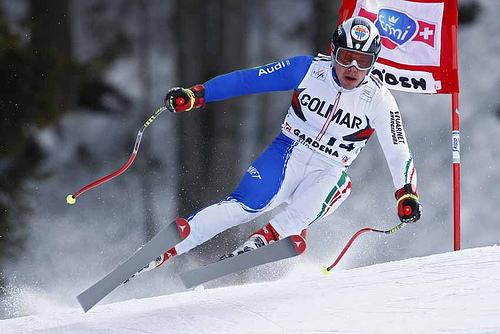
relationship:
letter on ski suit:
[305, 95, 321, 115] [207, 41, 437, 261]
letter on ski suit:
[315, 99, 334, 118] [141, 47, 461, 294]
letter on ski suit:
[310, 93, 318, 112] [111, 27, 462, 258]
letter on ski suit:
[338, 117, 350, 130] [174, 32, 444, 270]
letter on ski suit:
[348, 114, 361, 134] [158, 41, 424, 255]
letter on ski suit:
[288, 120, 302, 143] [135, 19, 440, 268]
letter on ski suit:
[302, 129, 305, 144] [188, 51, 459, 285]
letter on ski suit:
[305, 136, 322, 138] [193, 50, 438, 270]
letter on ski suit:
[310, 137, 319, 153] [177, 57, 432, 267]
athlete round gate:
[121, 16, 423, 295] [126, 3, 471, 283]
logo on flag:
[375, 8, 420, 51] [330, 1, 466, 99]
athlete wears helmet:
[121, 16, 423, 295] [326, 10, 384, 71]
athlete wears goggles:
[121, 16, 423, 295] [328, 46, 375, 71]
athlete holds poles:
[121, 16, 423, 295] [52, 81, 421, 281]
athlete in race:
[121, 16, 423, 295] [6, 4, 498, 331]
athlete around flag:
[121, 16, 423, 295] [328, 1, 468, 261]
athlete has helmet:
[121, 16, 423, 295] [324, 4, 389, 73]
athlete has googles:
[121, 16, 423, 295] [332, 41, 381, 71]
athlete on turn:
[121, 16, 423, 295] [52, 130, 499, 304]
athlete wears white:
[121, 16, 423, 295] [297, 79, 418, 231]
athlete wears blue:
[121, 16, 423, 295] [199, 44, 315, 213]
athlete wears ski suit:
[121, 16, 423, 295] [166, 54, 416, 263]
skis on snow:
[72, 208, 308, 318] [21, 274, 493, 332]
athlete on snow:
[137, 14, 431, 281] [97, 264, 378, 331]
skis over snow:
[72, 208, 308, 318] [26, 275, 402, 331]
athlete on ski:
[121, 16, 423, 295] [72, 210, 317, 322]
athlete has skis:
[121, 16, 423, 295] [34, 214, 315, 325]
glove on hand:
[169, 78, 209, 145] [154, 72, 204, 128]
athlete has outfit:
[121, 16, 423, 295] [209, 38, 431, 331]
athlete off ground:
[121, 16, 423, 295] [125, 237, 232, 331]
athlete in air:
[121, 16, 423, 295] [168, 25, 259, 56]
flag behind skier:
[330, 5, 474, 121] [170, 3, 448, 332]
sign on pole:
[376, 1, 485, 109] [434, 115, 481, 211]